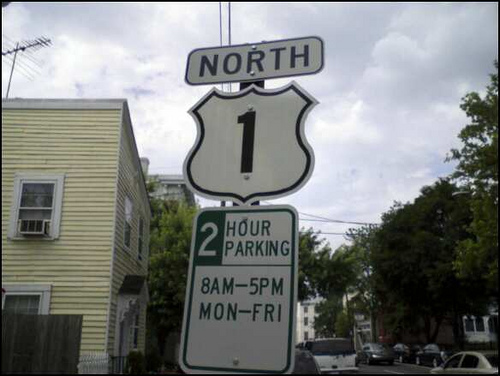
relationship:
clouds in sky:
[0, 0, 500, 261] [325, 6, 490, 185]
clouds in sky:
[0, 0, 500, 261] [104, 55, 474, 266]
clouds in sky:
[330, 33, 446, 118] [55, 50, 471, 235]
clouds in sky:
[0, 0, 500, 261] [112, 53, 474, 241]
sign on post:
[179, 32, 329, 86] [227, 42, 267, 374]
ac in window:
[18, 219, 49, 238] [12, 175, 67, 235]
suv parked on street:
[296, 335, 358, 374] [323, 357, 439, 372]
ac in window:
[16, 218, 47, 235] [16, 181, 54, 236]